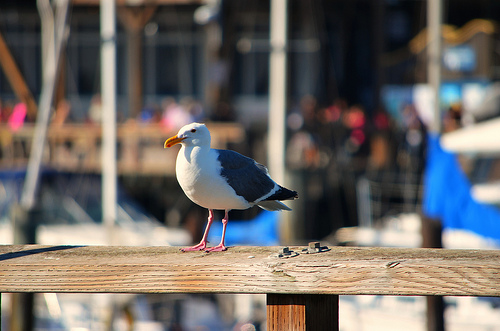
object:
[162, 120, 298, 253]
bird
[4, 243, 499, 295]
wood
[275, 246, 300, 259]
bolt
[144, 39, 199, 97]
window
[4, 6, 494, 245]
back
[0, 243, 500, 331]
rail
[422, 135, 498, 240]
material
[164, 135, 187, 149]
beak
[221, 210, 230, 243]
legs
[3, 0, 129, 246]
support beam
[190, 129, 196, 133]
eye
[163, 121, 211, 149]
head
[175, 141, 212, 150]
neck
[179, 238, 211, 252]
foot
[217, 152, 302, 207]
wing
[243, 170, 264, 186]
feather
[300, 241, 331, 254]
bolt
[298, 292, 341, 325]
shadow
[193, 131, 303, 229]
shadow